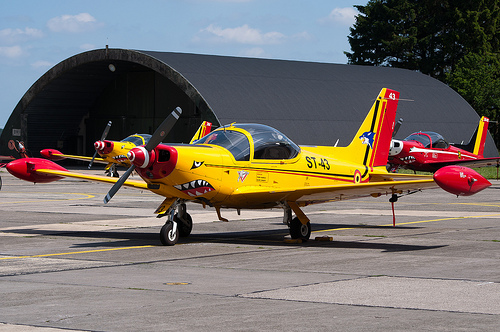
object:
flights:
[39, 120, 212, 177]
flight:
[2, 87, 497, 245]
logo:
[358, 128, 377, 150]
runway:
[2, 164, 482, 330]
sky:
[1, 0, 167, 41]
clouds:
[1, 10, 111, 64]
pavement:
[2, 249, 492, 303]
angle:
[82, 102, 201, 261]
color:
[397, 117, 486, 243]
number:
[320, 159, 331, 172]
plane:
[387, 115, 499, 174]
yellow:
[284, 176, 300, 186]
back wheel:
[291, 216, 313, 239]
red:
[441, 171, 459, 182]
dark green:
[393, 17, 426, 40]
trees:
[350, 3, 477, 73]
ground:
[14, 245, 464, 329]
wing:
[230, 165, 491, 208]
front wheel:
[160, 220, 180, 244]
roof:
[192, 122, 299, 148]